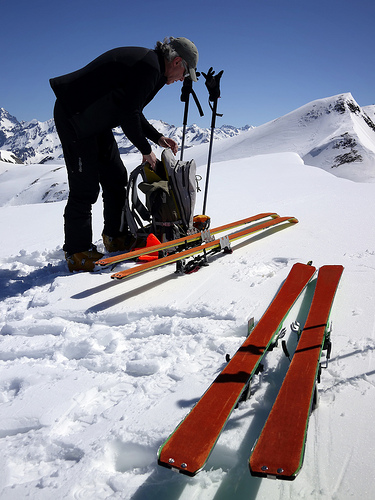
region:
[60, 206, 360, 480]
two sets of red skis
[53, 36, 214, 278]
man looking in backpack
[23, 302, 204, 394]
footprints made in snow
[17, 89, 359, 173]
snow covered mountains in the background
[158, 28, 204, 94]
man wearing grey baseball hat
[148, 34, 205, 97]
man with sunglasses on his face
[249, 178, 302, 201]
ground covered with snow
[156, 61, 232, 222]
two black ski poles stuck into snow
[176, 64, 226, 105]
black gloves on handles of ski poles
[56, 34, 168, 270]
man wearing black winter jacket and pants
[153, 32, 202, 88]
The man has gray hair.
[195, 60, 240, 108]
A glove is on the ski pole.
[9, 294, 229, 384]
Tracks in the snow.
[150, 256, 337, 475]
The skis are auburn.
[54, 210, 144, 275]
The man is wearing boots.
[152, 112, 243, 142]
A mountain range.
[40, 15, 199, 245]
The man is dressed in dark clothing.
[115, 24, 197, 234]
The man is looking through the backpack.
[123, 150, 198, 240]
A gray backpack.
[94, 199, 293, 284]
The skis are upside down.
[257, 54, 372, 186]
snow on a mountain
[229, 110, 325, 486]
red skiis in the snow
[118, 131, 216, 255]
a grey backpack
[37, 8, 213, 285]
a man with sunglasses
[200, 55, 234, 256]
a ski pole in the snow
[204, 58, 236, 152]
gloves on a ski pole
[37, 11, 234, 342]
a man wearing a hat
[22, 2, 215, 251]
a man with grey hair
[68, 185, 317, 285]
a set of orange skis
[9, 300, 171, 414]
feet tracks in the snow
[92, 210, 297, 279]
a pair of wood skis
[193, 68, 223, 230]
a man's right ski pole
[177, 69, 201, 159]
a man's left ski pole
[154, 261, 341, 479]
a pair of wooden skis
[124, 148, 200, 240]
a man's grey back pack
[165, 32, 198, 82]
a man's baseball cap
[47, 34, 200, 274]
a man standing in the snow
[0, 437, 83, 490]
a footprint in the snow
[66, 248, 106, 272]
a man's boot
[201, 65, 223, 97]
a man's right glove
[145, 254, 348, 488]
a pair of red skis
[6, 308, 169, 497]
foot prints in the snow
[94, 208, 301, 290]
a pair of red skis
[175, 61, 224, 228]
a pair of black ski poles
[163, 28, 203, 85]
a light grey cap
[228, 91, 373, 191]
a snowy mountain in the distance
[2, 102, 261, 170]
a snowy mountain range in the distance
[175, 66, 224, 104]
a pair of black gloves